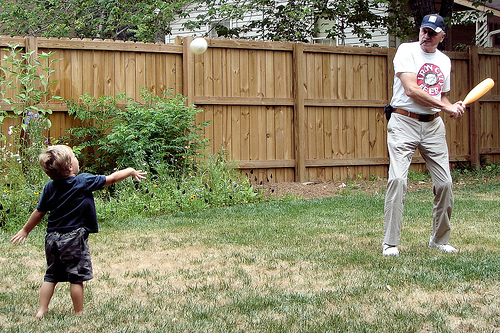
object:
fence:
[0, 35, 389, 182]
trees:
[0, 0, 500, 38]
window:
[310, 11, 340, 47]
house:
[164, 0, 390, 47]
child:
[5, 143, 148, 321]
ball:
[187, 37, 208, 55]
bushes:
[56, 87, 267, 214]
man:
[381, 13, 494, 259]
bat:
[461, 77, 494, 110]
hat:
[420, 13, 446, 34]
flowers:
[144, 144, 275, 214]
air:
[0, 1, 282, 98]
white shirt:
[389, 42, 452, 116]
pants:
[382, 112, 454, 246]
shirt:
[35, 172, 105, 232]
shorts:
[41, 227, 93, 283]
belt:
[392, 107, 440, 122]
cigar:
[420, 40, 427, 46]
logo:
[415, 62, 446, 97]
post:
[292, 42, 304, 182]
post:
[181, 35, 195, 120]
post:
[24, 37, 38, 166]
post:
[468, 44, 481, 168]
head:
[418, 13, 447, 49]